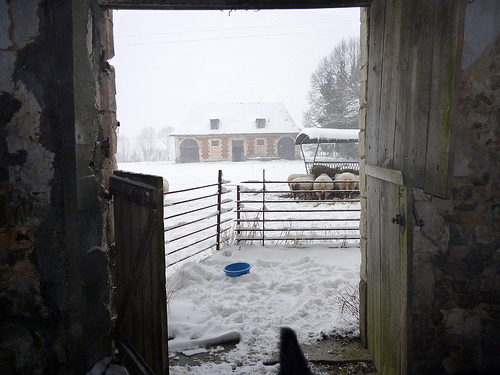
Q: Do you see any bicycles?
A: No, there are no bicycles.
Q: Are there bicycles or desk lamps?
A: No, there are no bicycles or desk lamps.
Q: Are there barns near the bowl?
A: Yes, there is a barn near the bowl.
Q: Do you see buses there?
A: No, there are no buses.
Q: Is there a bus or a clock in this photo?
A: No, there are no buses or clocks.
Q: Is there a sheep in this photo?
A: Yes, there is a sheep.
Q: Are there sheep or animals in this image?
A: Yes, there is a sheep.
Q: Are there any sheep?
A: Yes, there is a sheep.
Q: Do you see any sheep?
A: Yes, there is a sheep.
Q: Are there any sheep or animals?
A: Yes, there is a sheep.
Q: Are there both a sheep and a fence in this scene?
A: Yes, there are both a sheep and a fence.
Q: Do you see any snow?
A: Yes, there is snow.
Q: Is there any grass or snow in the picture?
A: Yes, there is snow.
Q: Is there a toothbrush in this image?
A: No, there are no toothbrushes.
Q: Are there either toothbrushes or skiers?
A: No, there are no toothbrushes or skiers.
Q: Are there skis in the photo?
A: No, there are no skis.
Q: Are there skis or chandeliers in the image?
A: No, there are no skis or chandeliers.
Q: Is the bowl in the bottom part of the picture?
A: Yes, the bowl is in the bottom of the image.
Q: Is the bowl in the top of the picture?
A: No, the bowl is in the bottom of the image.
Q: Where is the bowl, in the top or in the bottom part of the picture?
A: The bowl is in the bottom of the image.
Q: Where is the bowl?
A: The bowl is in the snow.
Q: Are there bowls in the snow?
A: Yes, there is a bowl in the snow.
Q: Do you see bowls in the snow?
A: Yes, there is a bowl in the snow.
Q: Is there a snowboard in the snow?
A: No, there is a bowl in the snow.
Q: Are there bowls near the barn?
A: Yes, there is a bowl near the barn.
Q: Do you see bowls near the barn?
A: Yes, there is a bowl near the barn.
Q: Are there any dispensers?
A: No, there are no dispensers.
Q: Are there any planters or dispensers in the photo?
A: No, there are no dispensers or planters.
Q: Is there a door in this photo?
A: Yes, there is a door.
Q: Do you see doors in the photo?
A: Yes, there is a door.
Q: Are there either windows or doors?
A: Yes, there is a door.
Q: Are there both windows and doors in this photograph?
A: Yes, there are both a door and a window.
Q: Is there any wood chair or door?
A: Yes, there is a wood door.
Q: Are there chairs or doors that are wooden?
A: Yes, the door is wooden.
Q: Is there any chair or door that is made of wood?
A: Yes, the door is made of wood.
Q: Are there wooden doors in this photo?
A: Yes, there is a wood door.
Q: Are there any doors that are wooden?
A: Yes, there is a door that is wooden.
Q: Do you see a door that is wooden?
A: Yes, there is a door that is wooden.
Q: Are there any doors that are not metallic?
A: Yes, there is a wooden door.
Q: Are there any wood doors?
A: Yes, there is a door that is made of wood.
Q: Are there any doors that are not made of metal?
A: Yes, there is a door that is made of wood.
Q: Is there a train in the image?
A: No, there are no trains.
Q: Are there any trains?
A: No, there are no trains.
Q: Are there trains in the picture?
A: No, there are no trains.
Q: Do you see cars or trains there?
A: No, there are no trains or cars.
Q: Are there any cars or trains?
A: No, there are no trains or cars.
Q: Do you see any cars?
A: No, there are no cars.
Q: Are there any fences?
A: Yes, there is a fence.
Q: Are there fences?
A: Yes, there is a fence.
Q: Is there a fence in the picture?
A: Yes, there is a fence.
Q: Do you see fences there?
A: Yes, there is a fence.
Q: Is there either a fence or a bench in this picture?
A: Yes, there is a fence.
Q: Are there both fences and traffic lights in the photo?
A: No, there is a fence but no traffic lights.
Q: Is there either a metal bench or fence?
A: Yes, there is a metal fence.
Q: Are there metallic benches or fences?
A: Yes, there is a metal fence.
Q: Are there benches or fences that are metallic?
A: Yes, the fence is metallic.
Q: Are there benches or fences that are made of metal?
A: Yes, the fence is made of metal.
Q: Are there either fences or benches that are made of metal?
A: Yes, the fence is made of metal.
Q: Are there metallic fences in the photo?
A: Yes, there is a metal fence.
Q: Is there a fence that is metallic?
A: Yes, there is a fence that is metallic.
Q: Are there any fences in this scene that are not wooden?
A: Yes, there is a metallic fence.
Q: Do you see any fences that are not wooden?
A: Yes, there is a metallic fence.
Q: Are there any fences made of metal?
A: Yes, there is a fence that is made of metal.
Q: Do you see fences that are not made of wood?
A: Yes, there is a fence that is made of metal.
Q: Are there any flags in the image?
A: No, there are no flags.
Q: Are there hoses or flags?
A: No, there are no flags or hoses.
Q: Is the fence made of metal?
A: Yes, the fence is made of metal.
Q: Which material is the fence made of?
A: The fence is made of metal.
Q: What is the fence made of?
A: The fence is made of metal.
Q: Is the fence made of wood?
A: No, the fence is made of metal.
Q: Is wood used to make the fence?
A: No, the fence is made of metal.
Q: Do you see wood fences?
A: No, there is a fence but it is made of metal.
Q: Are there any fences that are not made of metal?
A: No, there is a fence but it is made of metal.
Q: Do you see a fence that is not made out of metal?
A: No, there is a fence but it is made of metal.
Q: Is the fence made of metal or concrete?
A: The fence is made of metal.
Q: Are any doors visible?
A: Yes, there is a door.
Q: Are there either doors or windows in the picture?
A: Yes, there is a door.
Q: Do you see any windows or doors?
A: Yes, there is a door.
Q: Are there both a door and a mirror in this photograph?
A: No, there is a door but no mirrors.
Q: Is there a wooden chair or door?
A: Yes, there is a wood door.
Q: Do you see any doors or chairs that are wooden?
A: Yes, the door is wooden.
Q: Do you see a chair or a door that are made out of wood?
A: Yes, the door is made of wood.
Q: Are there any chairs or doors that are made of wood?
A: Yes, the door is made of wood.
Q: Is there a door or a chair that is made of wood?
A: Yes, the door is made of wood.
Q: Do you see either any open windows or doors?
A: Yes, there is an open door.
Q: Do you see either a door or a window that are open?
A: Yes, the door is open.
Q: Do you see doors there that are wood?
A: Yes, there is a wood door.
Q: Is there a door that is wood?
A: Yes, there is a wood door.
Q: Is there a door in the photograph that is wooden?
A: Yes, there is a door that is wooden.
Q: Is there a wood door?
A: Yes, there is a door that is made of wood.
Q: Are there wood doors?
A: Yes, there is a door that is made of wood.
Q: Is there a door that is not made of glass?
A: Yes, there is a door that is made of wood.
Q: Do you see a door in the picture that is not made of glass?
A: Yes, there is a door that is made of wood.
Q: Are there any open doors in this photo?
A: Yes, there is an open door.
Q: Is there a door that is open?
A: Yes, there is a door that is open.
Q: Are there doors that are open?
A: Yes, there is a door that is open.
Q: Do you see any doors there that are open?
A: Yes, there is a door that is open.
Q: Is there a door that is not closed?
A: Yes, there is a open door.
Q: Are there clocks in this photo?
A: No, there are no clocks.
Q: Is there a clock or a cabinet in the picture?
A: No, there are no clocks or cabinets.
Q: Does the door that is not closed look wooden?
A: Yes, the door is wooden.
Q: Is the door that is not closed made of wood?
A: Yes, the door is made of wood.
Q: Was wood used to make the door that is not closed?
A: Yes, the door is made of wood.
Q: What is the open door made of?
A: The door is made of wood.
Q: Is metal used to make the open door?
A: No, the door is made of wood.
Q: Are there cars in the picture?
A: No, there are no cars.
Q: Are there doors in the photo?
A: Yes, there is a door.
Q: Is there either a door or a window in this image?
A: Yes, there is a door.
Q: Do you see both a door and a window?
A: Yes, there are both a door and a window.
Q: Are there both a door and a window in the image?
A: Yes, there are both a door and a window.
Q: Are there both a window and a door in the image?
A: Yes, there are both a door and a window.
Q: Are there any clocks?
A: No, there are no clocks.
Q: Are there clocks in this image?
A: No, there are no clocks.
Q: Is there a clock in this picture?
A: No, there are no clocks.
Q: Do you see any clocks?
A: No, there are no clocks.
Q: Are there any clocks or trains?
A: No, there are no clocks or trains.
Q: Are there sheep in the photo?
A: Yes, there is a sheep.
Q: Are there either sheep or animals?
A: Yes, there is a sheep.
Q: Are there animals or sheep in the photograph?
A: Yes, there is a sheep.